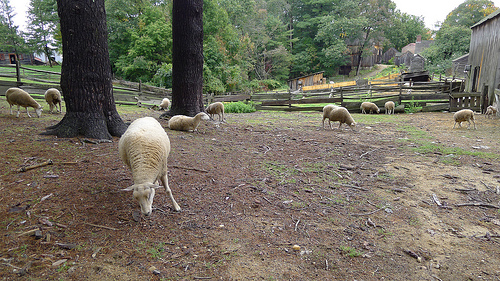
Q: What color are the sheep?
A: White.